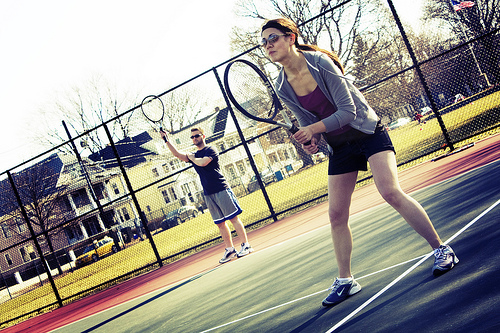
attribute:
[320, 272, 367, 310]
shoes — blue, white